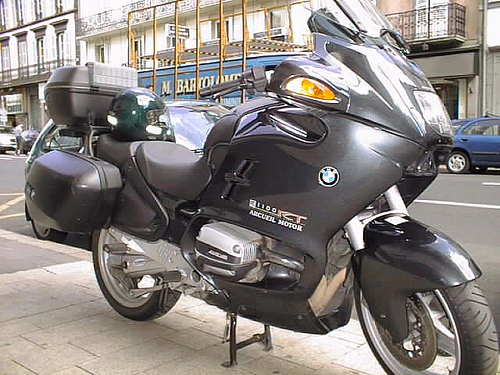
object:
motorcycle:
[29, 0, 500, 374]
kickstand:
[222, 310, 273, 369]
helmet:
[107, 85, 178, 143]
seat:
[99, 132, 212, 202]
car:
[439, 115, 499, 174]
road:
[0, 152, 500, 336]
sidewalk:
[0, 227, 458, 374]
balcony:
[384, 4, 467, 51]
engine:
[189, 221, 271, 286]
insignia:
[314, 163, 344, 189]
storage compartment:
[42, 60, 139, 131]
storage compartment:
[25, 150, 124, 234]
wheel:
[350, 267, 499, 375]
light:
[282, 75, 339, 103]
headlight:
[409, 88, 453, 138]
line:
[415, 199, 499, 211]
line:
[482, 181, 499, 187]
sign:
[135, 54, 298, 102]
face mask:
[148, 107, 177, 142]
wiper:
[334, 1, 366, 36]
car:
[23, 147, 116, 236]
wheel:
[90, 229, 183, 323]